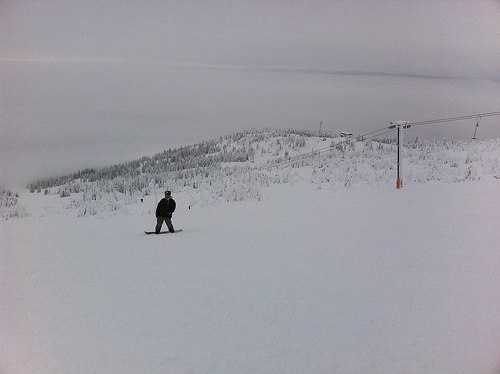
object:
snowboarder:
[154, 187, 177, 235]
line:
[0, 59, 498, 83]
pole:
[393, 117, 400, 188]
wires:
[395, 111, 496, 125]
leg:
[163, 216, 176, 230]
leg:
[154, 215, 164, 231]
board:
[143, 226, 184, 236]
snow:
[0, 130, 498, 373]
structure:
[338, 129, 353, 139]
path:
[0, 209, 500, 372]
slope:
[0, 178, 498, 373]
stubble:
[320, 166, 326, 173]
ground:
[0, 208, 500, 373]